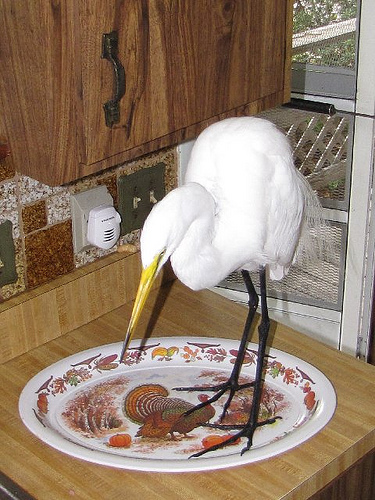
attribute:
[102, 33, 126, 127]
handle — brass, older, metal, black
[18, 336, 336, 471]
plate — white, ceramic, fall-themed, paper, thanksgiving-themed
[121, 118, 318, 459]
crane — large, white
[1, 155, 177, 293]
tiles — black, brown, white, grainy, earth-toned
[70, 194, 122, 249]
plug — white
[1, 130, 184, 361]
wall — tile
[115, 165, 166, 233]
light panel — black, two-switch, gray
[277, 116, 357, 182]
lattice — wooden, white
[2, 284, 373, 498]
countertop — wood, wooden, brown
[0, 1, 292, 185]
cabinet — wooden, wall-hung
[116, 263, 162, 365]
beak — yellow, long, pointy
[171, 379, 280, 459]
feet — black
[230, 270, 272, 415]
legs — long, black, skinny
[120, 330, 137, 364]
tip — black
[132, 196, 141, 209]
switch — up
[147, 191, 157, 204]
switch — down